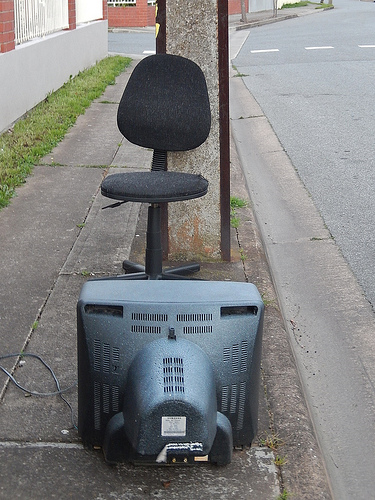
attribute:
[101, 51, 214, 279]
chair — black 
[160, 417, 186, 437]
tag — white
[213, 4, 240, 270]
metal — rusted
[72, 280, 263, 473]
tv — old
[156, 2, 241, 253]
post — brick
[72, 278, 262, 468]
television — abandoned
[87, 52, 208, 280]
chair — Black 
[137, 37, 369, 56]
area — crossing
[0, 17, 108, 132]
fence base — concrete